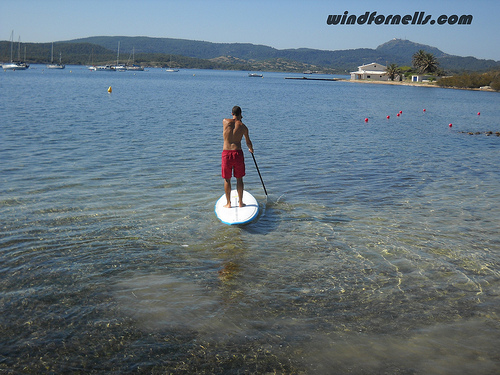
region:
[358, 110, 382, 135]
red ball in blue waters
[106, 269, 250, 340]
small puddle in water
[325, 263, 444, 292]
tiny white waves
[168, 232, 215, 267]
small white pebble in water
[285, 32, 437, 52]
mountain wave in the distance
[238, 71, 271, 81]
small blue boat in the water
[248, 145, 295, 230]
black paddle in man's hand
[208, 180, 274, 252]
white paddle board in water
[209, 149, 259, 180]
man wearing red shorts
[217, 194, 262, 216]
man bare feet on board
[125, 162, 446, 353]
The water is crystal clear.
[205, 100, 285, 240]
The man is paddleboarding.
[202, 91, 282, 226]
The man is holding a paddle.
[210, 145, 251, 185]
The man is wearing red swimming trunks.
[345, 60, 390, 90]
A house.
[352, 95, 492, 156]
Small buoys.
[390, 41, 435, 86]
Palm trees in the distance.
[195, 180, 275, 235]
The board is blue and white.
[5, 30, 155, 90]
Sailboats in the distance.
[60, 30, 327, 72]
The terrain is very hilly.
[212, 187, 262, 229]
a surfing item used in oceans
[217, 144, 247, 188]
a red color shorts for comfort wear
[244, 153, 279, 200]
a stick used to push water back to move boat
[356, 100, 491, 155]
the red color danger symbol used to indicate to do not cross the limit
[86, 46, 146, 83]
the couple of boats parked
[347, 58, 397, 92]
the sea shore house to live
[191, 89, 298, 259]
a person with red shorts trying to sail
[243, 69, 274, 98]
a boat going for a ride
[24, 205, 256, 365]
the under water plants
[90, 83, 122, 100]
a yellow color item shows to do not cross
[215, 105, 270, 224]
a man is paddle boarding in shallow water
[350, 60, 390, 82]
a white building is on an island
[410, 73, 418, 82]
a gazebo is on the island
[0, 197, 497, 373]
sea grass is in the shallow water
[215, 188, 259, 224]
the paddle board is white with a blue stripe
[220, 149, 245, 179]
the mans swim trunks are red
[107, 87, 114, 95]
a yellow buoy marks the channel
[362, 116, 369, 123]
red lobster trap buoys are near the shore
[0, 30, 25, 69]
sailboats are moored in the bay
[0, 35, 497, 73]
hills are in the horizon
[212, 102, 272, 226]
Man on a paddle board.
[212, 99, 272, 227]
Man in red swim trunks.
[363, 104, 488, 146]
Red buoys floating in the water.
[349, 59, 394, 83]
White house by the water's edge.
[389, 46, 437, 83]
Palm trees.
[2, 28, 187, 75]
Sailboats with their sails down.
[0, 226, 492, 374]
Shallow water.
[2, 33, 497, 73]
Mountains.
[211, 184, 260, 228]
White paddle board edged in blue.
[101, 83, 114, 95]
Yellow buoy floating alone.